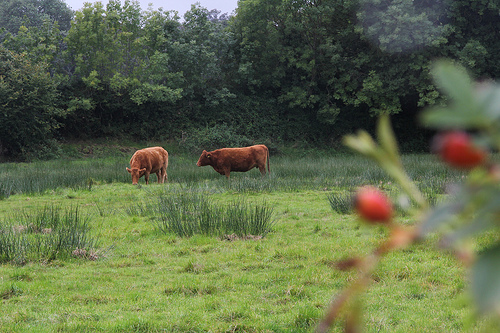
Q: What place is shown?
A: It is a field.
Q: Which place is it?
A: It is a field.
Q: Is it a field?
A: Yes, it is a field.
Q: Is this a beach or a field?
A: It is a field.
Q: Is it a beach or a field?
A: It is a field.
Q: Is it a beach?
A: No, it is a field.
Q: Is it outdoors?
A: Yes, it is outdoors.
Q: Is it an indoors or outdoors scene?
A: It is outdoors.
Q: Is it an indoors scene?
A: No, it is outdoors.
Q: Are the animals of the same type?
A: Yes, all the animals are cows.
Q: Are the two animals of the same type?
A: Yes, all the animals are cows.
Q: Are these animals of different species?
A: No, all the animals are cows.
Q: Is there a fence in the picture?
A: No, there are no fences.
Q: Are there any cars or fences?
A: No, there are no fences or cars.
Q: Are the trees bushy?
A: Yes, the trees are bushy.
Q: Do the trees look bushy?
A: Yes, the trees are bushy.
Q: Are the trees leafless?
A: No, the trees are bushy.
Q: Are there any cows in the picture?
A: Yes, there is a cow.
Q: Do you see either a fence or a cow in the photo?
A: Yes, there is a cow.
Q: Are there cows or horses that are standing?
A: Yes, the cow is standing.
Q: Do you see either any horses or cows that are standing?
A: Yes, the cow is standing.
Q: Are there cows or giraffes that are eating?
A: Yes, the cow is eating.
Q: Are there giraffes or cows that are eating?
A: Yes, the cow is eating.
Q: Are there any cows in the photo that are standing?
A: Yes, there is a cow that is standing.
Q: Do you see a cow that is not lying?
A: Yes, there is a cow that is standing .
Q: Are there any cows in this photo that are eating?
A: Yes, there is a cow that is eating.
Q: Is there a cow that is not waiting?
A: Yes, there is a cow that is eating.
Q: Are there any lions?
A: No, there are no lions.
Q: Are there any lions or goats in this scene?
A: No, there are no lions or goats.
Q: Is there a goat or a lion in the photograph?
A: No, there are no lions or goats.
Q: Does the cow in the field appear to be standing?
A: Yes, the cow is standing.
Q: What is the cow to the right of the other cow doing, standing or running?
A: The cow is standing.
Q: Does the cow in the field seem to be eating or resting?
A: The cow is eating.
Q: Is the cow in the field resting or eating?
A: The cow is eating.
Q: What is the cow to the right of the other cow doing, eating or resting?
A: The cow is eating.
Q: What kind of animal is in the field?
A: The animal is a cow.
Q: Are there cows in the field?
A: Yes, there is a cow in the field.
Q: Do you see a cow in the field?
A: Yes, there is a cow in the field.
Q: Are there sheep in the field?
A: No, there is a cow in the field.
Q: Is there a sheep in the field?
A: No, there is a cow in the field.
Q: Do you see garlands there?
A: No, there are no garlands.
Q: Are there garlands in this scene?
A: No, there are no garlands.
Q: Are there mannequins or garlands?
A: No, there are no garlands or mannequins.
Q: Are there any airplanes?
A: No, there are no airplanes.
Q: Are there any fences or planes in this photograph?
A: No, there are no planes or fences.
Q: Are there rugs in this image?
A: No, there are no rugs.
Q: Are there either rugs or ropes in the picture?
A: No, there are no rugs or ropes.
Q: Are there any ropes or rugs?
A: No, there are no rugs or ropes.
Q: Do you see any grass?
A: Yes, there is grass.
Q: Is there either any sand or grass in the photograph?
A: Yes, there is grass.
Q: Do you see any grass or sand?
A: Yes, there is grass.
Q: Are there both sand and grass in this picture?
A: No, there is grass but no sand.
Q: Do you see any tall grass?
A: Yes, there is tall grass.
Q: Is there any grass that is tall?
A: Yes, there is grass that is tall.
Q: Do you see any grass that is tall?
A: Yes, there is grass that is tall.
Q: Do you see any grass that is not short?
A: Yes, there is tall grass.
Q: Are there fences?
A: No, there are no fences.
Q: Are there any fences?
A: No, there are no fences.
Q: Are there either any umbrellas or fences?
A: No, there are no fences or umbrellas.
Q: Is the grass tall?
A: Yes, the grass is tall.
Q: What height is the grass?
A: The grass is tall.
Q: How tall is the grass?
A: The grass is tall.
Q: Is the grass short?
A: No, the grass is tall.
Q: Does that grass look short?
A: No, the grass is tall.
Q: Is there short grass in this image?
A: No, there is grass but it is tall.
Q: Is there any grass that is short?
A: No, there is grass but it is tall.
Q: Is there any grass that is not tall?
A: No, there is grass but it is tall.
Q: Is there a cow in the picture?
A: Yes, there is a cow.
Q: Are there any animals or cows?
A: Yes, there is a cow.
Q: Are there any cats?
A: No, there are no cats.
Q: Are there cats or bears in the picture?
A: No, there are no cats or bears.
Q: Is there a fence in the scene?
A: No, there are no fences.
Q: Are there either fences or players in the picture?
A: No, there are no fences or players.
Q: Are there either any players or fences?
A: No, there are no fences or players.